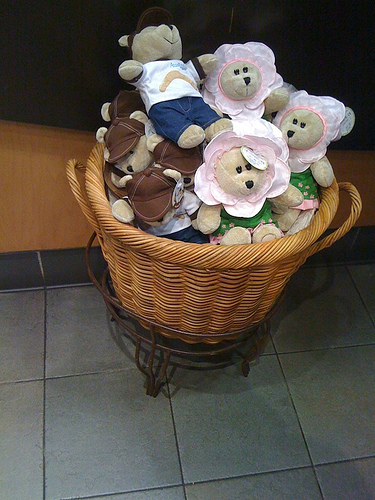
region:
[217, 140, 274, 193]
head of a teddy bear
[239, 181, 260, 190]
nose of a teddy bear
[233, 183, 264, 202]
mouth of a teddy bear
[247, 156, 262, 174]
eye of a teddy bear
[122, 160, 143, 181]
nose of a teddy bear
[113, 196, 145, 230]
leg of a teddy bear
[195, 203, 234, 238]
arm of a teddy bear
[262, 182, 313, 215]
arm of a teddy bear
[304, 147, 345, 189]
arm of a teddy bear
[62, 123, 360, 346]
a large brown wicker basket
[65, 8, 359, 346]
a basket full of bears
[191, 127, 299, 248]
a bear with a flower head piece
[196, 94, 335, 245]
two bears wearing green dresses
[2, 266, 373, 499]
a grey tiled floor with dark grouting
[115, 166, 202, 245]
a bear with a brown ball cap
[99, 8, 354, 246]
a pile of eight teddy bears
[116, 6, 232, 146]
a teddy bear wearing a white shirt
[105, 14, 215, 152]
this is a doll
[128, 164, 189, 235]
this is a doll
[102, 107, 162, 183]
this is a doll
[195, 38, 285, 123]
this is a doll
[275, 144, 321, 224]
this is a doll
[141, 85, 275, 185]
this is a doll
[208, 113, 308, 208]
this is a doll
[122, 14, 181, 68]
head of a teddy bear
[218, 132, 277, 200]
head of a teddy bear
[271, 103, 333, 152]
head of a teddy bear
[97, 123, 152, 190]
head of a teddy bear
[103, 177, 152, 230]
leg of a teddy bear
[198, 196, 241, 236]
arm of a teddy bear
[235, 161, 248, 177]
eye of a teddy bear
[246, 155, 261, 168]
eye of a teddy bear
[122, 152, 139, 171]
nose of a teddy bear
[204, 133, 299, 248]
teddy bear in the basket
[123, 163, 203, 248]
teddy bear in the basket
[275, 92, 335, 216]
teddy bear in the basket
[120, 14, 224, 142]
teddy bear in the basket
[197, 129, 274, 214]
pink cloth on the teddy bear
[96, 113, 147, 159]
teddy bear wearing a bear hat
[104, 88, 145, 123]
teddy bear wearing a bear hat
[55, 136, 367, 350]
a brown basket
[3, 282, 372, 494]
a gray floor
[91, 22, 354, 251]
a group of teddy bears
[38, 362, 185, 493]
a gray tile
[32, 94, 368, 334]
a scene inside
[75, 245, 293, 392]
a brown holder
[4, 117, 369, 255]
a brown floor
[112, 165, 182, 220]
a brown hat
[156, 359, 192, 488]
a crack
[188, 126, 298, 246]
cute stuffed bear in the basket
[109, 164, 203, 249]
cute stuffed bear in the basket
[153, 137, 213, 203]
cute stuffed bear in the basket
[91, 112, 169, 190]
cute stuffed bear in the basket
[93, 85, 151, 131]
cute stuffed bear in the basket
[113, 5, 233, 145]
cute stuffed bear in the basket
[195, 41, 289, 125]
cute stuffed bear in the basket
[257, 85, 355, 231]
cute stuffed bear in the basket